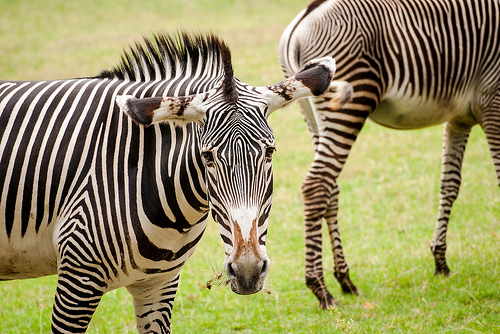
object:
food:
[201, 262, 271, 295]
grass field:
[0, 0, 499, 332]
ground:
[397, 157, 438, 198]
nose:
[227, 260, 269, 278]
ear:
[258, 56, 336, 115]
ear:
[115, 94, 209, 127]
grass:
[358, 184, 415, 226]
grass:
[1, 0, 102, 62]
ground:
[246, 88, 272, 117]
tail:
[280, 15, 354, 110]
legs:
[297, 99, 360, 296]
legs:
[300, 99, 379, 311]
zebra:
[275, 0, 499, 312]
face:
[200, 113, 277, 295]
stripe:
[391, 16, 414, 94]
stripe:
[399, 0, 433, 106]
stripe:
[417, 0, 432, 35]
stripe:
[447, 1, 459, 106]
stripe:
[442, 170, 461, 179]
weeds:
[371, 216, 423, 240]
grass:
[366, 278, 428, 332]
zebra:
[1, 27, 337, 333]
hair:
[73, 26, 240, 105]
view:
[114, 55, 338, 296]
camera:
[272, 244, 392, 318]